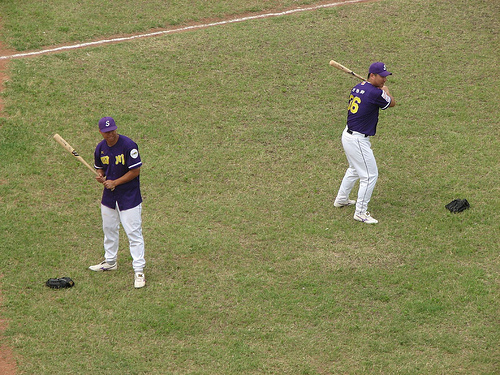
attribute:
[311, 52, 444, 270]
player — male, tall, brunette, blue, white, uniformed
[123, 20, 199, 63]
line — white